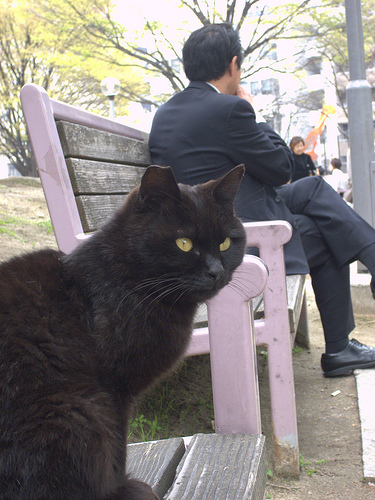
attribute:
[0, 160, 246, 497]
cat — black, large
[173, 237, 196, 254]
eye — green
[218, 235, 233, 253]
eye — green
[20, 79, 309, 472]
bench — pink, grey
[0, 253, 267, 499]
bench — pink, wooden, grey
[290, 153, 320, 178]
coat — black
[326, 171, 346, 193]
coat — white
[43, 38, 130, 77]
leaves — green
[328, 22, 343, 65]
leaves — green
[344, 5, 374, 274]
pole — gray, tall, metal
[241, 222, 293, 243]
arm — pink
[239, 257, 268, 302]
arm — pink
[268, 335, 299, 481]
leg — pink, rusty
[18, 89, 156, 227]
back — weathered, wood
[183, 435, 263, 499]
slat — wooden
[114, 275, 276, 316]
whiskers — long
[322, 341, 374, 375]
shoe — black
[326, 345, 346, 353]
socks — black